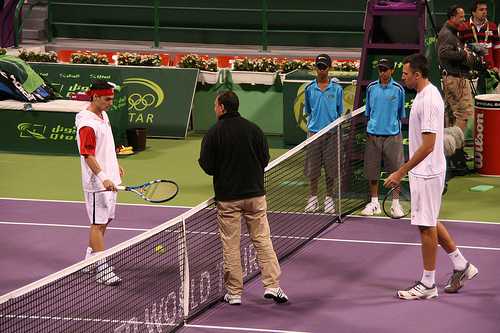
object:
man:
[74, 77, 129, 286]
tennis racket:
[111, 178, 179, 204]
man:
[198, 91, 290, 306]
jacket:
[196, 111, 271, 200]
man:
[302, 53, 344, 217]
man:
[362, 57, 407, 220]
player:
[384, 52, 480, 300]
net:
[0, 101, 372, 332]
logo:
[15, 120, 83, 142]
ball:
[154, 242, 166, 255]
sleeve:
[77, 124, 97, 160]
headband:
[84, 86, 118, 98]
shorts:
[303, 129, 345, 183]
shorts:
[361, 130, 409, 183]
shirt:
[301, 77, 343, 136]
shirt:
[363, 75, 405, 135]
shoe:
[304, 193, 319, 213]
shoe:
[320, 193, 340, 213]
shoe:
[359, 200, 384, 216]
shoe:
[388, 199, 406, 218]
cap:
[314, 52, 333, 69]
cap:
[373, 56, 395, 69]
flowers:
[68, 47, 109, 66]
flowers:
[114, 50, 165, 70]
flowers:
[174, 49, 219, 73]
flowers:
[227, 51, 284, 72]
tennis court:
[1, 132, 500, 332]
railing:
[12, 0, 499, 48]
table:
[1, 65, 131, 152]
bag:
[0, 54, 63, 104]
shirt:
[403, 81, 448, 177]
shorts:
[407, 168, 450, 224]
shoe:
[93, 261, 123, 287]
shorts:
[85, 186, 121, 225]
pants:
[215, 195, 284, 294]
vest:
[73, 108, 123, 190]